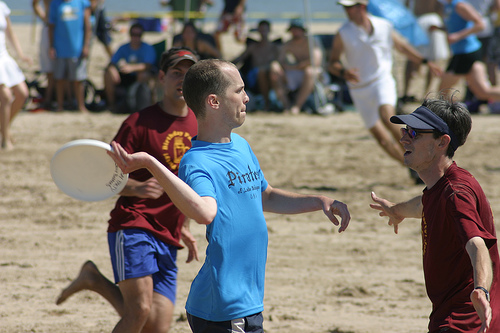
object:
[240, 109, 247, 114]
mouth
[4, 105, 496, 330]
sand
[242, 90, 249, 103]
nose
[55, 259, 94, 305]
foot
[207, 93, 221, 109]
ear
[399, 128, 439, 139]
sunglasses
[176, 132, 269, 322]
blue shirt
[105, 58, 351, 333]
man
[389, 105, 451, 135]
sunvisor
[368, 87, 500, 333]
man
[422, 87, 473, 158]
dark hair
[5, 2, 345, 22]
water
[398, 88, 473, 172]
head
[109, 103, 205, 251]
shirt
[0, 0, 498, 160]
spectators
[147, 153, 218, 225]
arm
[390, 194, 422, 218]
arm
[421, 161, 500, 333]
red shirt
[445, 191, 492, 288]
arms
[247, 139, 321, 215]
arms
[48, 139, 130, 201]
frisbee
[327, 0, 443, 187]
person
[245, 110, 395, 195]
beach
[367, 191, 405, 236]
hand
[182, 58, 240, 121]
hair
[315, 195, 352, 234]
hand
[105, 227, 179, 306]
blue shorts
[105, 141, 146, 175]
hand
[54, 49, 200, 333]
man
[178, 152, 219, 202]
sleeve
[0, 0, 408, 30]
background